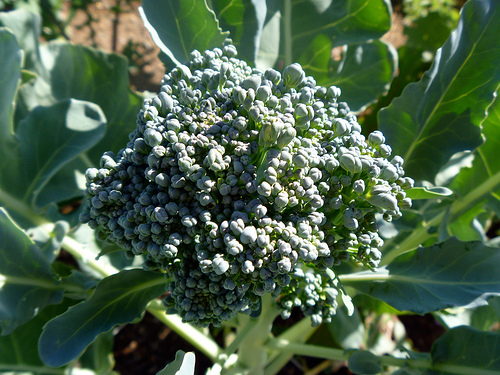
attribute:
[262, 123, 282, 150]
bud — green, swelling, open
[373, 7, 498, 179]
leaf — green, new, healthy, large, narrow, wide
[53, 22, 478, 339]
brocooli — green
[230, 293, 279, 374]
stalk — fat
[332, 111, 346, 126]
seedling — green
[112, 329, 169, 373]
dirt — wet, brown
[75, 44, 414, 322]
head — green, young, small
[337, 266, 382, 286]
stem — long, thick, yellow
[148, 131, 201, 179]
florets — tightly closed, fat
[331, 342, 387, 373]
leaf — curled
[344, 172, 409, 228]
flower bud — clustered